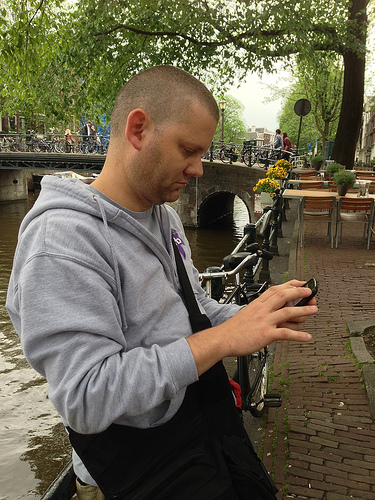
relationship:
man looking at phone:
[5, 62, 319, 496] [281, 278, 317, 311]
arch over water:
[195, 191, 250, 231] [183, 195, 249, 273]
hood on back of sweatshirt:
[13, 169, 173, 239] [4, 173, 248, 435]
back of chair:
[300, 195, 336, 212] [292, 193, 339, 257]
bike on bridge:
[220, 138, 258, 167] [165, 138, 292, 228]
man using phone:
[5, 62, 319, 496] [281, 278, 317, 311]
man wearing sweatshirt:
[5, 62, 319, 496] [4, 173, 248, 435]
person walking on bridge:
[272, 128, 282, 161] [165, 138, 292, 228]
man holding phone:
[5, 62, 319, 496] [281, 278, 317, 311]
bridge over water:
[165, 138, 292, 228] [183, 195, 249, 273]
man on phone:
[5, 62, 319, 496] [281, 278, 317, 311]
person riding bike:
[272, 128, 282, 161] [220, 138, 258, 167]